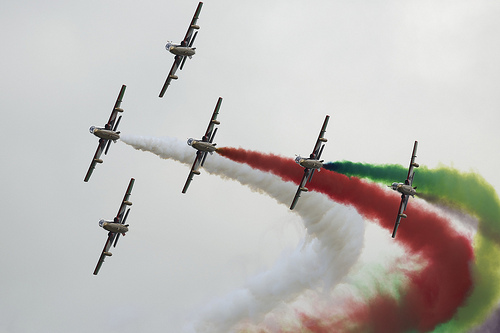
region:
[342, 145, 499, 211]
Green smoke coming out of plane.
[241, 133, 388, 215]
Red smoke coming out of plane.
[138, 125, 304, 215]
White smoke coming out of sky.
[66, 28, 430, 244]
6 planes flying close to one another.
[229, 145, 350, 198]
Red smoke coming out of plane.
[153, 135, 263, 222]
White smoke coming out of plane.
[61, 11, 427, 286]
6 planes flying in sky near each other.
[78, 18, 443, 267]
six acrobatic planes flying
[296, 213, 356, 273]
some white gas being released from a plane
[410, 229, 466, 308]
some red gas being released from a plane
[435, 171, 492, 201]
some green gas being released from a plane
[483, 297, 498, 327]
some purple gas being released from a plane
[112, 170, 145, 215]
a plane wing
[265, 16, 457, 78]
some very clear skies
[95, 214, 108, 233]
a plane propeller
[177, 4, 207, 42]
a plane wing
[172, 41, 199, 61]
a body of a plane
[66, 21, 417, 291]
the planes in flight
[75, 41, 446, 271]
six planes in the air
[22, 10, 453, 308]
the wide open sky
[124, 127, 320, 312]
the white smoke from the plane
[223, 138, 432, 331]
the red smoke from the plane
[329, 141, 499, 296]
the green smoke from the plane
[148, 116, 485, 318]
red white and green smoke from the planes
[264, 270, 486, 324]
where all the smoke mixes together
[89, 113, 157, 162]
plane putting out white smoke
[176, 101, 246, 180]
plane putting out red smoke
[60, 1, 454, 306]
group of planes flying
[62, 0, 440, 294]
group of planes flying in air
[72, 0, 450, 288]
planes releasing colored gas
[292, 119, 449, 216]
green colored gas coming out of plane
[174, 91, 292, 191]
red colored gas behind plane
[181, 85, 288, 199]
red colored gas coming out of plane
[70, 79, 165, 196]
white colored gas coming out of plane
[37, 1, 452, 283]
planes flying in formation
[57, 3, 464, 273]
squad of planes flying together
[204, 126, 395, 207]
three colors mixing in air